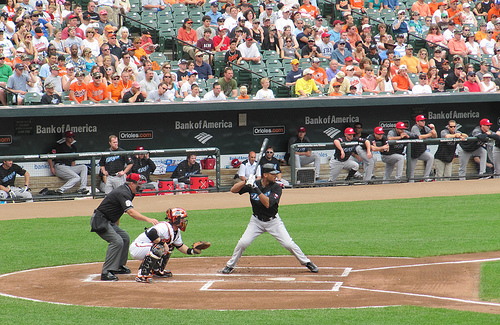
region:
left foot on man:
[303, 258, 323, 271]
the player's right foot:
[224, 256, 236, 280]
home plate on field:
[262, 269, 297, 286]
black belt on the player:
[250, 211, 282, 223]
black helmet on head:
[263, 162, 277, 172]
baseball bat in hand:
[253, 135, 271, 171]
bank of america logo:
[171, 115, 237, 145]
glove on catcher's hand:
[191, 235, 208, 257]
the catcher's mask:
[167, 204, 192, 230]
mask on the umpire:
[127, 165, 151, 193]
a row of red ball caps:
[333, 113, 496, 138]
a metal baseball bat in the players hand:
[241, 129, 270, 196]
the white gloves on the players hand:
[244, 171, 258, 188]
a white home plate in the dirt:
[259, 271, 300, 283]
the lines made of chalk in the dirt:
[79, 260, 359, 299]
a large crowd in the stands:
[1, 4, 463, 103]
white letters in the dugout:
[168, 118, 235, 134]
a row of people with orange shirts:
[66, 79, 124, 105]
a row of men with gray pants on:
[323, 143, 491, 189]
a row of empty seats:
[132, 5, 202, 28]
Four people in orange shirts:
[66, 69, 133, 104]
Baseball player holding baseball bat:
[218, 135, 320, 277]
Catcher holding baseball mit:
[127, 204, 213, 285]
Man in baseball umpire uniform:
[87, 170, 160, 285]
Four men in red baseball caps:
[325, 112, 437, 186]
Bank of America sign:
[168, 119, 235, 132]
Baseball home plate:
[262, 274, 299, 286]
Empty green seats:
[121, 5, 179, 42]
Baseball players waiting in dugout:
[284, 89, 499, 192]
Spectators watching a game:
[0, 0, 499, 110]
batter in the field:
[209, 163, 317, 272]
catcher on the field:
[125, 205, 190, 277]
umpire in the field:
[84, 176, 132, 273]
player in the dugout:
[329, 123, 372, 184]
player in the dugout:
[360, 118, 385, 179]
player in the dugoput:
[392, 126, 417, 193]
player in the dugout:
[413, 118, 444, 188]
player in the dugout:
[425, 95, 459, 182]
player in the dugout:
[482, 125, 495, 177]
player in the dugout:
[102, 126, 125, 183]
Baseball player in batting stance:
[222, 139, 321, 276]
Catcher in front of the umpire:
[127, 206, 209, 283]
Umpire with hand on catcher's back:
[91, 170, 158, 283]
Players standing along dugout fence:
[331, 115, 497, 190]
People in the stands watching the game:
[0, 0, 499, 107]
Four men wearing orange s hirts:
[70, 69, 138, 104]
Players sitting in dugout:
[1, 130, 201, 202]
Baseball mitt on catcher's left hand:
[188, 237, 210, 258]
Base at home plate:
[269, 265, 298, 286]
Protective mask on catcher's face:
[168, 205, 190, 239]